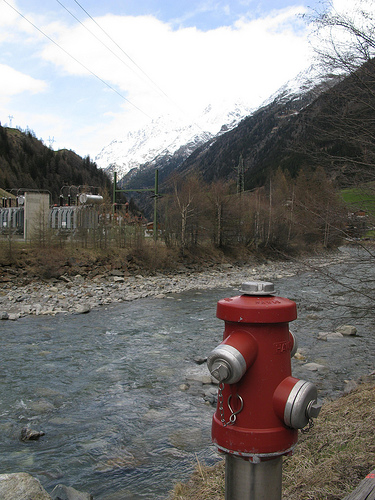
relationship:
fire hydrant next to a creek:
[206, 281, 322, 500] [0, 246, 374, 499]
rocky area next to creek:
[0, 252, 351, 320] [0, 246, 374, 499]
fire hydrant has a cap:
[206, 281, 322, 500] [238, 281, 277, 296]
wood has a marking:
[339, 469, 375, 500] [364, 472, 374, 479]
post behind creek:
[153, 169, 159, 242] [0, 246, 374, 499]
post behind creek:
[111, 172, 117, 214] [0, 246, 374, 499]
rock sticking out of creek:
[317, 330, 344, 341] [0, 246, 374, 499]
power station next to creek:
[0, 168, 158, 240] [0, 246, 374, 499]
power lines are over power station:
[0, 0, 205, 133] [0, 168, 158, 240]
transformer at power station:
[51, 185, 105, 241] [0, 168, 158, 240]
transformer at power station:
[0, 187, 53, 239] [0, 168, 158, 240]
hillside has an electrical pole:
[0, 126, 161, 224] [7, 114, 15, 128]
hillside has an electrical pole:
[0, 126, 161, 224] [46, 135, 57, 150]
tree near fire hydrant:
[268, 0, 374, 350] [206, 281, 322, 500]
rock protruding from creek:
[317, 330, 344, 341] [0, 246, 374, 499]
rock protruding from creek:
[335, 324, 357, 336] [0, 246, 374, 499]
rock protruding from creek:
[301, 362, 327, 372] [0, 246, 374, 499]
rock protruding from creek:
[193, 355, 208, 364] [0, 246, 374, 499]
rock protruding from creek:
[186, 373, 220, 385] [0, 246, 374, 499]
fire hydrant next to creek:
[206, 281, 322, 500] [0, 246, 374, 499]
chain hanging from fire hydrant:
[217, 381, 244, 426] [206, 281, 322, 500]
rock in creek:
[335, 324, 357, 336] [0, 246, 374, 499]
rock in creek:
[317, 330, 344, 341] [0, 246, 374, 499]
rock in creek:
[301, 362, 327, 372] [0, 246, 374, 499]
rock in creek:
[193, 355, 208, 364] [0, 246, 374, 499]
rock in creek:
[186, 373, 220, 385] [0, 246, 374, 499]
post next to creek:
[153, 169, 159, 242] [0, 246, 374, 499]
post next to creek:
[111, 172, 117, 214] [0, 246, 374, 499]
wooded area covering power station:
[0, 167, 352, 283] [0, 168, 158, 240]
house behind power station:
[141, 219, 166, 237] [0, 168, 158, 240]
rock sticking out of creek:
[335, 324, 357, 336] [0, 246, 374, 499]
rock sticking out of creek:
[301, 362, 327, 372] [0, 246, 374, 499]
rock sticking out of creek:
[193, 355, 208, 364] [0, 246, 374, 499]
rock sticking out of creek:
[186, 373, 220, 385] [0, 246, 374, 499]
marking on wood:
[364, 472, 374, 479] [339, 469, 375, 500]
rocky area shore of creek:
[0, 252, 351, 320] [0, 246, 374, 499]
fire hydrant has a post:
[206, 281, 322, 500] [225, 454, 283, 500]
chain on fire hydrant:
[217, 381, 244, 426] [206, 281, 322, 500]